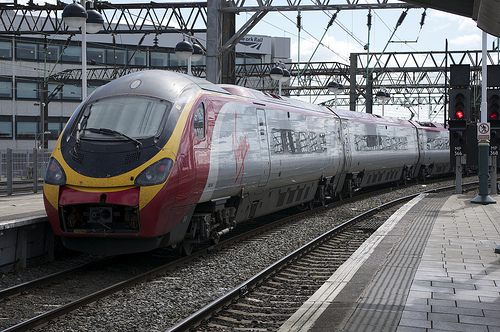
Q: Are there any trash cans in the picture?
A: No, there are no trash cans.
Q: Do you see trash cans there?
A: No, there are no trash cans.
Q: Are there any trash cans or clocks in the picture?
A: No, there are no trash cans or clocks.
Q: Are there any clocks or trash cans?
A: No, there are no trash cans or clocks.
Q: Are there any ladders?
A: No, there are no ladders.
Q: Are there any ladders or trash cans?
A: No, there are no ladders or trash cans.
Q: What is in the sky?
A: The clouds are in the sky.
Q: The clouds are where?
A: The clouds are in the sky.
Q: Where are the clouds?
A: The clouds are in the sky.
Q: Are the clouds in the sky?
A: Yes, the clouds are in the sky.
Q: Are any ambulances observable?
A: No, there are no ambulances.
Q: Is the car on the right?
A: Yes, the car is on the right of the image.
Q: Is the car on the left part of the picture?
A: No, the car is on the right of the image.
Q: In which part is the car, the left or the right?
A: The car is on the right of the image.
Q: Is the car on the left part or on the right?
A: The car is on the right of the image.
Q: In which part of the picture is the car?
A: The car is on the right of the image.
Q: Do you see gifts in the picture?
A: No, there are no gifts.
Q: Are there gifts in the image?
A: No, there are no gifts.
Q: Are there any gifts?
A: No, there are no gifts.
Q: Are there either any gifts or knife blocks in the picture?
A: No, there are no gifts or knife blocks.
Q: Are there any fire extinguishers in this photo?
A: No, there are no fire extinguishers.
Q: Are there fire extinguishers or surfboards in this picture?
A: No, there are no fire extinguishers or surfboards.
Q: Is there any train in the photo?
A: Yes, there is a train.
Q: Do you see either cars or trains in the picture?
A: Yes, there is a train.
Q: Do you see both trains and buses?
A: No, there is a train but no buses.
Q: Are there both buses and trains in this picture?
A: No, there is a train but no buses.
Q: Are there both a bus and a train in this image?
A: No, there is a train but no buses.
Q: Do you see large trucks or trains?
A: Yes, there is a large train.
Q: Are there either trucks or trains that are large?
A: Yes, the train is large.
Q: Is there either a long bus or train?
A: Yes, there is a long train.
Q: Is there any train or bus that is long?
A: Yes, the train is long.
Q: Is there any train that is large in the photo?
A: Yes, there is a large train.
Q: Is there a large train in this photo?
A: Yes, there is a large train.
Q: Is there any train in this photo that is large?
A: Yes, there is a train that is large.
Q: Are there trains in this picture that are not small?
A: Yes, there is a large train.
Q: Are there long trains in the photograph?
A: Yes, there is a long train.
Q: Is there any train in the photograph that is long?
A: Yes, there is a train that is long.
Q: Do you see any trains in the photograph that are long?
A: Yes, there is a train that is long.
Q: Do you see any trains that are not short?
A: Yes, there is a long train.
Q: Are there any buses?
A: No, there are no buses.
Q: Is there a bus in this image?
A: No, there are no buses.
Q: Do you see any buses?
A: No, there are no buses.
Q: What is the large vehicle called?
A: The vehicle is a train.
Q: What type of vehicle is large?
A: The vehicle is a train.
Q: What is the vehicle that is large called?
A: The vehicle is a train.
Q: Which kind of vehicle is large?
A: The vehicle is a train.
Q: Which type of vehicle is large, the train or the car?
A: The train is large.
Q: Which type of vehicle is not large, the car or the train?
A: The car is not large.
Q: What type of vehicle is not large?
A: The vehicle is a car.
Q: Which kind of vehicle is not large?
A: The vehicle is a car.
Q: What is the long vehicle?
A: The vehicle is a train.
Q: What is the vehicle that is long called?
A: The vehicle is a train.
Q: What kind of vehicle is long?
A: The vehicle is a train.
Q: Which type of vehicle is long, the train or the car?
A: The train is long.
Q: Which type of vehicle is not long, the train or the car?
A: The car is not long.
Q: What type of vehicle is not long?
A: The vehicle is a car.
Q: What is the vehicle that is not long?
A: The vehicle is a car.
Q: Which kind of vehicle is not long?
A: The vehicle is a car.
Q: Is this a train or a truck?
A: This is a train.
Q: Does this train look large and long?
A: Yes, the train is large and long.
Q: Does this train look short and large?
A: No, the train is large but long.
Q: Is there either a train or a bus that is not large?
A: No, there is a train but it is large.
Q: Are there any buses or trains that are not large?
A: No, there is a train but it is large.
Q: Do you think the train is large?
A: Yes, the train is large.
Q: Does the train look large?
A: Yes, the train is large.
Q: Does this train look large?
A: Yes, the train is large.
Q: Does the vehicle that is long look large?
A: Yes, the train is large.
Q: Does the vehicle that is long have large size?
A: Yes, the train is large.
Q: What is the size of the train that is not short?
A: The train is large.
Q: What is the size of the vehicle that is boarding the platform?
A: The train is large.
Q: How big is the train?
A: The train is large.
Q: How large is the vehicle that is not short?
A: The train is large.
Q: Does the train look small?
A: No, the train is large.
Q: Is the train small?
A: No, the train is large.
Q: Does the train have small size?
A: No, the train is large.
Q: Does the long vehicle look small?
A: No, the train is large.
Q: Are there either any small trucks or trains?
A: No, there is a train but it is large.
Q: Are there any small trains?
A: No, there is a train but it is large.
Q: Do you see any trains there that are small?
A: No, there is a train but it is large.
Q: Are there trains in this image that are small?
A: No, there is a train but it is large.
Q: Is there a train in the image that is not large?
A: No, there is a train but it is large.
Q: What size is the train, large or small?
A: The train is large.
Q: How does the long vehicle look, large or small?
A: The train is large.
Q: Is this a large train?
A: Yes, this is a large train.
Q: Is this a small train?
A: No, this is a large train.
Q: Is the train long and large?
A: Yes, the train is long and large.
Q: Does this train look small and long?
A: No, the train is long but large.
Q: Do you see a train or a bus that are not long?
A: No, there is a train but it is long.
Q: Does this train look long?
A: Yes, the train is long.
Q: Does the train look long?
A: Yes, the train is long.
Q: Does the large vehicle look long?
A: Yes, the train is long.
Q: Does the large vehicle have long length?
A: Yes, the train is long.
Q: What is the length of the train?
A: The train is long.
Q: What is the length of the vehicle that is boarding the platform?
A: The train is long.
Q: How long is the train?
A: The train is long.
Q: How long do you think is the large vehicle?
A: The train is long.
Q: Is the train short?
A: No, the train is long.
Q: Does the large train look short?
A: No, the train is long.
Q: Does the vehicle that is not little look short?
A: No, the train is long.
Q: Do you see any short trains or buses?
A: No, there is a train but it is long.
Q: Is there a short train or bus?
A: No, there is a train but it is long.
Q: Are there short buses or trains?
A: No, there is a train but it is long.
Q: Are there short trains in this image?
A: No, there is a train but it is long.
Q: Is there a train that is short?
A: No, there is a train but it is long.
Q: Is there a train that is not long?
A: No, there is a train but it is long.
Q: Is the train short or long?
A: The train is long.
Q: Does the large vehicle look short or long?
A: The train is long.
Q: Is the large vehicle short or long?
A: The train is long.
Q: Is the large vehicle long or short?
A: The train is long.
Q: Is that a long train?
A: Yes, that is a long train.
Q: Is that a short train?
A: No, that is a long train.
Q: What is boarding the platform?
A: The train is boarding the platform.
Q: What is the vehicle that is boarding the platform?
A: The vehicle is a train.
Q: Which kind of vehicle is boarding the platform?
A: The vehicle is a train.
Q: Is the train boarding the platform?
A: Yes, the train is boarding the platform.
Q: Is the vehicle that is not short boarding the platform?
A: Yes, the train is boarding the platform.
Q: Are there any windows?
A: Yes, there are windows.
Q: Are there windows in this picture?
A: Yes, there are windows.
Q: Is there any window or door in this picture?
A: Yes, there are windows.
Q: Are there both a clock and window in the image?
A: No, there are windows but no clocks.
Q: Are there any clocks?
A: No, there are no clocks.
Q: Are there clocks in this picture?
A: No, there are no clocks.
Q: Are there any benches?
A: No, there are no benches.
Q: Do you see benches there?
A: No, there are no benches.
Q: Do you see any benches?
A: No, there are no benches.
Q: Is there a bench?
A: No, there are no benches.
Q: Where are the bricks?
A: The bricks are on the sidewalk.